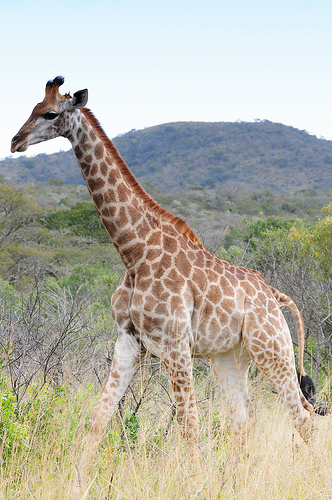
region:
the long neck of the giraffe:
[83, 145, 160, 247]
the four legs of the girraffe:
[93, 334, 297, 474]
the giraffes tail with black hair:
[275, 287, 327, 397]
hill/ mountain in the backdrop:
[123, 120, 329, 201]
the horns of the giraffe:
[42, 76, 69, 99]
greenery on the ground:
[3, 375, 79, 469]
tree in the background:
[1, 185, 30, 271]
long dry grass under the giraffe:
[151, 424, 325, 497]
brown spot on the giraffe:
[122, 250, 139, 264]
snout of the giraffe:
[8, 119, 65, 154]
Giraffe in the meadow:
[6, 72, 327, 496]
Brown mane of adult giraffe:
[78, 104, 214, 252]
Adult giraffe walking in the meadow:
[3, 71, 325, 486]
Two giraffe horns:
[40, 69, 62, 93]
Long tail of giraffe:
[275, 287, 324, 404]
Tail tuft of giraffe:
[296, 372, 327, 414]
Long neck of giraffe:
[72, 118, 166, 257]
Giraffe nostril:
[8, 134, 16, 140]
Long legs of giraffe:
[67, 319, 329, 493]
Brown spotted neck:
[49, 121, 188, 263]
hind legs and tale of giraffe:
[247, 291, 316, 443]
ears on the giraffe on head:
[43, 77, 89, 108]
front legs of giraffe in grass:
[66, 341, 200, 496]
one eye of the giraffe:
[40, 110, 60, 122]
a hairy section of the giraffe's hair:
[121, 153, 140, 208]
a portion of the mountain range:
[144, 119, 325, 189]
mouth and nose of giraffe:
[5, 132, 26, 153]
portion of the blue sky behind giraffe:
[108, 4, 330, 120]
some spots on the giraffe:
[90, 162, 117, 208]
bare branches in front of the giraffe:
[0, 287, 89, 375]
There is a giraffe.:
[9, 72, 328, 491]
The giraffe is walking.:
[4, 60, 325, 494]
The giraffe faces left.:
[0, 72, 324, 493]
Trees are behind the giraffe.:
[220, 207, 330, 395]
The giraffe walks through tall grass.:
[2, 377, 329, 497]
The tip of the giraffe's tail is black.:
[295, 362, 325, 412]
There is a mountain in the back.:
[3, 114, 330, 224]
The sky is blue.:
[2, 2, 331, 129]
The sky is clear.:
[1, 1, 330, 137]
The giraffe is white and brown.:
[61, 110, 316, 475]